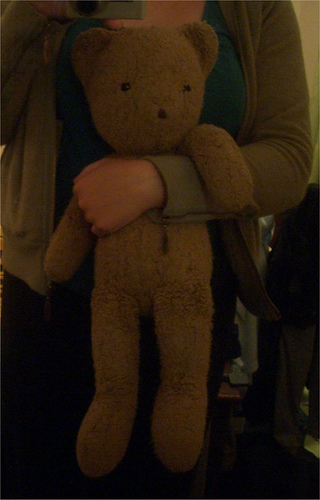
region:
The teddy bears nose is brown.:
[154, 104, 164, 118]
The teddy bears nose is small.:
[155, 104, 164, 115]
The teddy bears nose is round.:
[156, 109, 165, 115]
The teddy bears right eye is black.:
[114, 80, 130, 91]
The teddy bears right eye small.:
[114, 76, 124, 86]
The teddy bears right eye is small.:
[118, 80, 134, 90]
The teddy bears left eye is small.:
[181, 81, 191, 90]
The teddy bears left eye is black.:
[178, 80, 189, 90]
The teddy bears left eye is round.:
[178, 77, 192, 93]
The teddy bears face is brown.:
[70, 16, 218, 153]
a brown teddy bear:
[69, 39, 262, 253]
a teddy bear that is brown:
[51, 41, 190, 321]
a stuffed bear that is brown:
[70, 28, 296, 335]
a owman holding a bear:
[15, 93, 317, 439]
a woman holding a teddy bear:
[63, 31, 286, 344]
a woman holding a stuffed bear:
[25, 35, 279, 383]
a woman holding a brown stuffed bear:
[71, 19, 265, 426]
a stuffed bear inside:
[50, 53, 248, 285]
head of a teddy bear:
[68, 15, 227, 170]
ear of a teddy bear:
[61, 23, 111, 87]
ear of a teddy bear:
[174, 15, 234, 68]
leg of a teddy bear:
[132, 279, 247, 395]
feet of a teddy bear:
[53, 394, 156, 480]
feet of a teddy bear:
[125, 390, 240, 475]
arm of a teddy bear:
[37, 211, 93, 283]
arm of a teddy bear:
[180, 111, 260, 199]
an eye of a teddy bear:
[104, 74, 140, 102]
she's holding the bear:
[113, 149, 155, 174]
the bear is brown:
[176, 317, 194, 354]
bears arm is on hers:
[194, 147, 220, 197]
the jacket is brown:
[265, 54, 285, 87]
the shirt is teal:
[221, 57, 242, 79]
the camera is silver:
[120, 5, 130, 14]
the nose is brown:
[156, 108, 166, 118]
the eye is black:
[120, 79, 132, 94]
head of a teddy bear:
[48, 15, 229, 158]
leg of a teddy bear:
[75, 293, 170, 393]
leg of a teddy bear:
[129, 311, 248, 404]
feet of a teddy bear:
[128, 383, 233, 472]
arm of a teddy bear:
[31, 195, 99, 278]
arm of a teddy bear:
[171, 118, 277, 209]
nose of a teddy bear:
[139, 97, 174, 133]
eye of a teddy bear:
[172, 78, 204, 105]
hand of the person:
[84, 162, 161, 228]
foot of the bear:
[151, 396, 201, 475]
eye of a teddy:
[116, 76, 134, 96]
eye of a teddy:
[180, 80, 192, 97]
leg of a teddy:
[68, 319, 128, 470]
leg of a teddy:
[151, 288, 202, 468]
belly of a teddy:
[100, 225, 197, 292]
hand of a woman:
[77, 152, 146, 238]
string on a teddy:
[152, 219, 179, 260]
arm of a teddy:
[186, 123, 250, 202]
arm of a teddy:
[38, 203, 93, 281]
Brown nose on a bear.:
[158, 107, 164, 117]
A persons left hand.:
[72, 155, 164, 237]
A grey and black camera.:
[63, 1, 145, 21]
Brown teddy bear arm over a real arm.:
[183, 122, 251, 212]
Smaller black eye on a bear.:
[182, 83, 190, 92]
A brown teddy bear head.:
[70, 20, 218, 155]